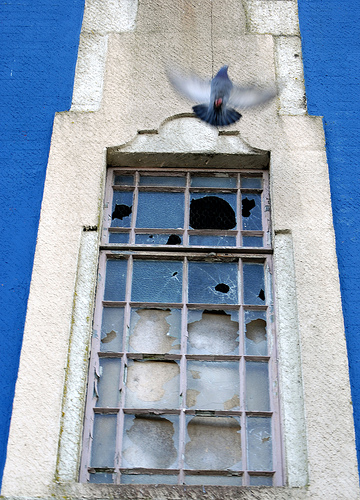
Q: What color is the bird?
A: Gray, white, and black.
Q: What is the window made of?
A: Glass.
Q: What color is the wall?
A: Blue.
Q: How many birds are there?
A: One.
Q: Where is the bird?
A: In front of the window.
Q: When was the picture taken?
A: Daytime.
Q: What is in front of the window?
A: The bird.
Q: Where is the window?
A: Behind the bird.